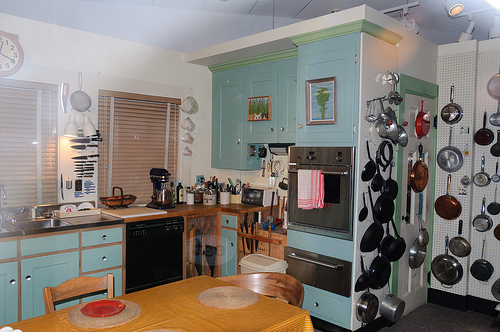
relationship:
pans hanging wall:
[378, 83, 484, 303] [365, 29, 484, 322]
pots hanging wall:
[370, 88, 484, 304] [365, 29, 484, 322]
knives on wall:
[60, 78, 101, 206] [62, 90, 104, 221]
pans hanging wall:
[431, 43, 500, 286] [365, 41, 475, 78]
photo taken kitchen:
[3, 6, 498, 331] [3, 6, 498, 331]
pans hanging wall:
[359, 70, 499, 325] [365, 29, 484, 322]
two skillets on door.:
[411, 168, 462, 220] [400, 87, 434, 310]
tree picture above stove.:
[302, 77, 343, 125] [291, 146, 354, 238]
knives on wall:
[70, 125, 101, 186] [60, 78, 101, 206]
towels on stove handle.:
[295, 164, 326, 213] [289, 168, 348, 178]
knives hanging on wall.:
[70, 125, 101, 186] [8, 14, 212, 207]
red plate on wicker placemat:
[81, 299, 123, 316] [66, 300, 145, 326]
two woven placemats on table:
[70, 287, 267, 330] [12, 275, 322, 331]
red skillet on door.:
[410, 95, 433, 137] [400, 87, 434, 310]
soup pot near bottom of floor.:
[382, 287, 403, 323] [379, 302, 499, 328]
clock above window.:
[1, 30, 26, 77] [3, 77, 59, 205]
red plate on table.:
[81, 299, 123, 316] [12, 275, 322, 331]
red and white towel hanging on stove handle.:
[295, 164, 326, 213] [289, 168, 348, 178]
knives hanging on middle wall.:
[70, 125, 101, 186] [60, 78, 101, 206]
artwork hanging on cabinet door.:
[245, 95, 274, 123] [247, 79, 280, 142]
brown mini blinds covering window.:
[98, 92, 183, 195] [3, 77, 59, 205]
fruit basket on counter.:
[95, 185, 137, 206] [101, 207, 265, 219]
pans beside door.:
[431, 43, 500, 286] [400, 87, 434, 310]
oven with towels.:
[291, 146, 354, 238] [295, 164, 326, 213]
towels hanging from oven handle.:
[295, 164, 326, 213] [289, 168, 348, 178]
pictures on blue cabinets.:
[248, 80, 335, 127] [210, 56, 360, 146]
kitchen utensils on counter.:
[184, 176, 242, 206] [101, 207, 265, 219]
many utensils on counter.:
[184, 176, 242, 206] [101, 207, 265, 219]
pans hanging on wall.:
[431, 43, 500, 286] [359, 70, 499, 325]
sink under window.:
[0, 209, 65, 235] [3, 77, 59, 205]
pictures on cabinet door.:
[248, 80, 335, 127] [247, 79, 280, 142]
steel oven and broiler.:
[291, 146, 354, 238] [285, 248, 354, 292]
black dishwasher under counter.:
[124, 221, 184, 290] [101, 207, 265, 219]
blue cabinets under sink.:
[0, 229, 81, 319] [0, 209, 65, 235]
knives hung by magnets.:
[70, 125, 101, 186] [77, 179, 95, 198]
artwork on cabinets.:
[245, 95, 274, 123] [247, 79, 280, 142]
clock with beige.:
[1, 30, 26, 77] [1, 33, 20, 42]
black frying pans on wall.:
[354, 143, 406, 292] [357, 34, 397, 328]